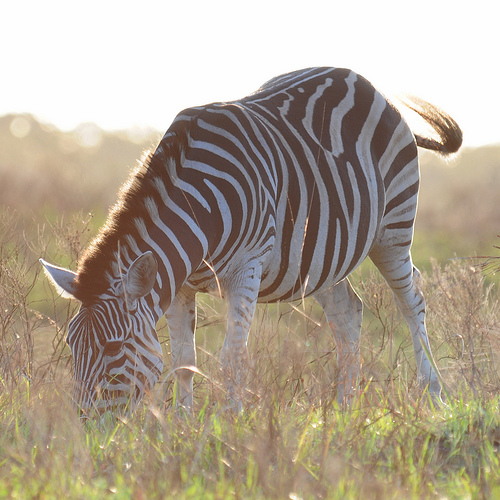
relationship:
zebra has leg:
[37, 65, 461, 433] [313, 277, 364, 414]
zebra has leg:
[37, 65, 461, 433] [368, 239, 446, 411]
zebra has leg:
[37, 65, 461, 433] [221, 262, 264, 410]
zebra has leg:
[37, 65, 461, 433] [163, 290, 198, 425]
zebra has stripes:
[37, 65, 461, 433] [227, 120, 382, 249]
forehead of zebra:
[71, 315, 103, 367] [37, 65, 461, 433]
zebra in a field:
[37, 65, 461, 433] [7, 212, 499, 499]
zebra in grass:
[37, 65, 461, 433] [274, 443, 370, 497]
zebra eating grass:
[50, 76, 475, 417] [6, 253, 488, 461]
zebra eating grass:
[37, 65, 461, 433] [0, 214, 497, 498]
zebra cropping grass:
[37, 65, 461, 433] [0, 214, 497, 498]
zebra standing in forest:
[37, 65, 461, 433] [2, 209, 462, 489]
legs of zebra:
[218, 321, 387, 463] [37, 65, 461, 433]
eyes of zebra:
[61, 328, 121, 360] [37, 65, 461, 433]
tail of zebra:
[393, 102, 463, 157] [37, 65, 461, 433]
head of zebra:
[38, 251, 163, 423] [37, 65, 461, 433]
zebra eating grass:
[37, 65, 461, 433] [91, 396, 258, 499]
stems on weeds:
[375, 319, 391, 356] [449, 257, 490, 346]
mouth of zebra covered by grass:
[59, 388, 151, 447] [58, 354, 175, 500]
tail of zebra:
[393, 93, 467, 156] [37, 65, 461, 433]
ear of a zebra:
[114, 237, 163, 334] [37, 65, 461, 433]